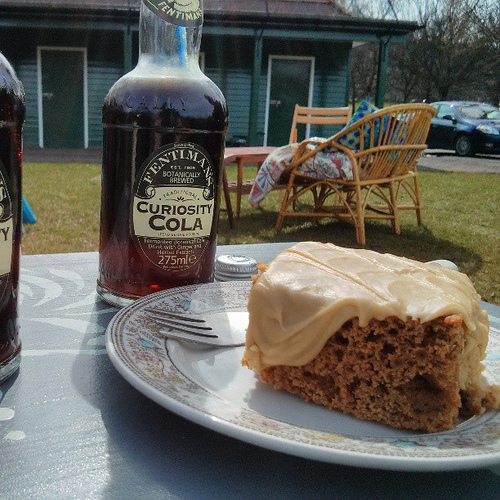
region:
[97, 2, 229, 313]
A mostly full bottle of curiosity Cola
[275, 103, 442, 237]
A wicker loveseat bench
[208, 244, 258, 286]
A silver bottlecap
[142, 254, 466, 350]
A fork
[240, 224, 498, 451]
A piece of light brown, messily frosted cake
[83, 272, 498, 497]
A decorative plate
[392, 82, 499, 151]
A parked car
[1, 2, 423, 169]
A greenish blue building with a long front porch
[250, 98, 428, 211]
Pillows and blankets piled on the bench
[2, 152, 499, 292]
A grassy area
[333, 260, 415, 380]
This is a piece of carrot cake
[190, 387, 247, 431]
This is a white plate with decorations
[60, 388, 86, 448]
This is a picnic table with graphics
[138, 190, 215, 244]
This bottle says "Curiosity Cola" on the side.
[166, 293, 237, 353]
There is a fork present in this photo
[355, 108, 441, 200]
There is a wicker piece of furniture here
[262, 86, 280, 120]
There is a gold handle on this door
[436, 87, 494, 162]
There is a car in the background of the photo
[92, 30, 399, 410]
Jackson Mingus took this photo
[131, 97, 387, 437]
This photo was taken in the state of Ohio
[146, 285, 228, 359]
fork on a plate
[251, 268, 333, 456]
a piece of cake on a plate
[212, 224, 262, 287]
top of a drink bottle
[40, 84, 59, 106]
a handle on a door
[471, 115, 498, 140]
headlight on a car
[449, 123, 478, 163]
a tire on a car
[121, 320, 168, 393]
design around the edge of a plate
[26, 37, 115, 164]
a door to the building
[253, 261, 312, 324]
brown icing on a cake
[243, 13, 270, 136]
a post holding up the roof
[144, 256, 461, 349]
A silver fork on a plate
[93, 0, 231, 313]
A glass soda bottle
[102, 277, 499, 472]
An ornate dessert plate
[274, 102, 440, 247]
A wooden love seat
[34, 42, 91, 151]
A green door with a white frame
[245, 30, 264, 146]
A green support pole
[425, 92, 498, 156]
A dark colored car in the parking lot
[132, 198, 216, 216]
the word curiosity written on the side of glass bottle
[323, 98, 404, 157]
A light an dark blue pillow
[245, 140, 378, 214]
A blue, pink, and white blanket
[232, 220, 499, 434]
A piece of cake with white icing.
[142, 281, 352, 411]
Fork laying on a plate.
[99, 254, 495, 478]
A round dessert plate.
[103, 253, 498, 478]
A plate with a decorative border.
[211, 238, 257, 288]
Silver cap for a bottle of drink.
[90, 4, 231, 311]
A bottle of something to drink.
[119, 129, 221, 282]
Label on the front of a bottle.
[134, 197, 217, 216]
The word CURIOSITY on the front of a bottle.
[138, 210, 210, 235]
The word COLA on the front of a bottle.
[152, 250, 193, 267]
275ml on front of a bottle.